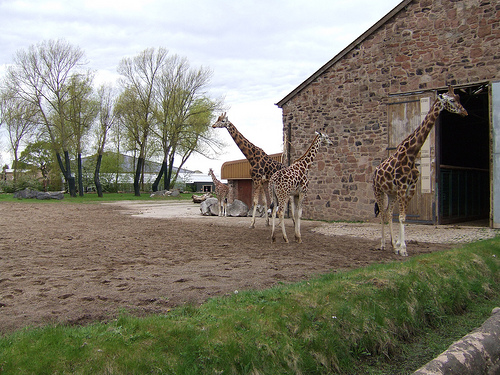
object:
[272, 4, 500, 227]
building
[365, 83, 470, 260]
giraffes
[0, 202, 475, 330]
dirt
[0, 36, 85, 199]
trees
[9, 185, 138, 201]
grass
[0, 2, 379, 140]
sky